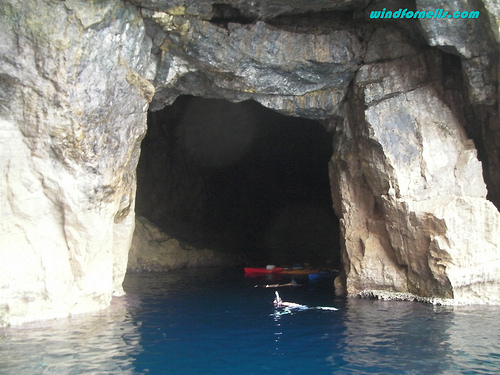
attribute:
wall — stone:
[325, 99, 496, 302]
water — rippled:
[7, 327, 133, 372]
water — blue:
[195, 283, 398, 349]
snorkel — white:
[270, 287, 283, 304]